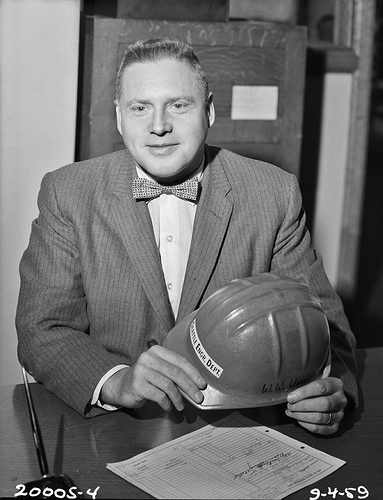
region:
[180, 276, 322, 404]
man holding a helmet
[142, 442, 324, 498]
a paper on the desk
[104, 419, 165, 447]
a table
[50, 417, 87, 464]
a shadow on the table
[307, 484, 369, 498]
the date of the picture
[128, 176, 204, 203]
man is wearing a tie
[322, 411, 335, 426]
man wearing a ring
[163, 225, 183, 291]
buttons shirt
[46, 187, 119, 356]
man wearing a suit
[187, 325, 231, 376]
label on the helmet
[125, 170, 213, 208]
Very lovely bow tie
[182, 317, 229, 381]
Black lettering on white tape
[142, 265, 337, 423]
Very large hard hat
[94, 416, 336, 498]
White invoice with black lettering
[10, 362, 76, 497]
Old fashiones pen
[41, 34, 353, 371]
Man holding a hard hat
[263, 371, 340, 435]
Wedding band on mans finger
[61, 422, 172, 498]
Reflection of man on desk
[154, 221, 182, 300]
Small buttions on a mans shirt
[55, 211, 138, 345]
Pen Striped on mans suit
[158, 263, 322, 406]
man is holding hard hat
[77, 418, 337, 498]
white spreadsheet paper in front of man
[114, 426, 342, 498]
writing is on spreadsheet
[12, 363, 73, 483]
black pen in holder next to paper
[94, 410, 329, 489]
paper is on dark table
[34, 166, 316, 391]
man is wearing striped jacket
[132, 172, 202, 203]
man wears checked bow tie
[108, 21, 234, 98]
man has short and light hair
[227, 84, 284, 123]
white label on box behind man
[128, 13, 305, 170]
wooden crate is behind man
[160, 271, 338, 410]
A hard hat with writing on the front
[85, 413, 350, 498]
Paperwork on the table with writing on it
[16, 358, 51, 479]
A writing pen in it's casing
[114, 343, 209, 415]
A man's hand holding a hat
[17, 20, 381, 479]
a black and white photo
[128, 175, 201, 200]
The bow tie has square's on it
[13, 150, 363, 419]
The man's blazer is pin striped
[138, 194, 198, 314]
The shirt under the man's jacket is white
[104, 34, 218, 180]
The man has a large head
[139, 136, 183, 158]
The man is smiling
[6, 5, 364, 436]
Man dress in suit with bowtie holding a construction helmet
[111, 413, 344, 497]
A piece of paper with printed lines and handwriting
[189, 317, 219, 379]
A label printed on a safety hat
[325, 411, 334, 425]
A tasteful wedding band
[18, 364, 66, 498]
Black pen upright in a pen holder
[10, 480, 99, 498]
Handwritten numbers on photo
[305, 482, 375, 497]
Handwritten date of photograph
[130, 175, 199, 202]
A small checkered bowtie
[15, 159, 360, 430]
A grey and black pinstripe suit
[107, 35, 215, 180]
Man has short hair cut and a smile on his face